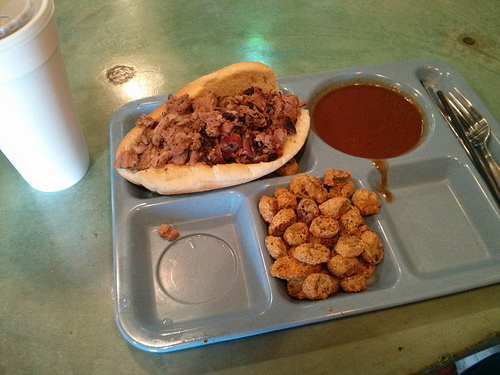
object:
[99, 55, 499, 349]
tray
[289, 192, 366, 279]
breadcrumbs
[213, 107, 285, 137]
meat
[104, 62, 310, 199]
sandwich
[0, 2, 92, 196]
cup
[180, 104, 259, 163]
chunk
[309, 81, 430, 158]
sauce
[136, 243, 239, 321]
part of tray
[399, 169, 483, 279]
empty part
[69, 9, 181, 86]
object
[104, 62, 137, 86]
dent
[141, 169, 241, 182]
bread